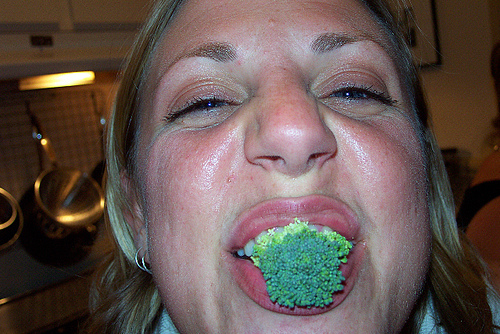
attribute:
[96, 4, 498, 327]
hair — light, blonde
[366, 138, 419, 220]
cheek — red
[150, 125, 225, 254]
cheek — red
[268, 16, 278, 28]
pimple — small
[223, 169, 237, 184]
pimple — small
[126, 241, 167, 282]
earring — silver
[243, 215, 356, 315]
broccoli — green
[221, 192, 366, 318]
lips — red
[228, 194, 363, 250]
lip — red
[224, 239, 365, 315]
lip — red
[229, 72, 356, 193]
nose — red